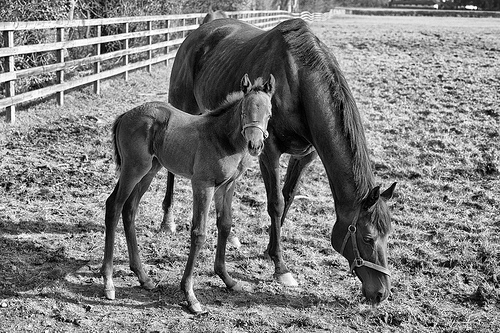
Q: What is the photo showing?
A: It is showing a pasture.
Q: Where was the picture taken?
A: It was taken at the pasture.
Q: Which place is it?
A: It is a pasture.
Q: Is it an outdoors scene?
A: Yes, it is outdoors.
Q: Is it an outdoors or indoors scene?
A: It is outdoors.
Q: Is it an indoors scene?
A: No, it is outdoors.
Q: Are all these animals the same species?
A: Yes, all the animals are horses.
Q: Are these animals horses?
A: Yes, all the animals are horses.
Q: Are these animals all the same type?
A: Yes, all the animals are horses.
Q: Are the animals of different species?
A: No, all the animals are horses.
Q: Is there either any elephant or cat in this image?
A: No, there are no cats or elephants.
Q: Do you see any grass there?
A: Yes, there is grass.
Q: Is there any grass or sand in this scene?
A: Yes, there is grass.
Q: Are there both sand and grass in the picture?
A: No, there is grass but no sand.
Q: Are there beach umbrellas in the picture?
A: No, there are no beach umbrellas.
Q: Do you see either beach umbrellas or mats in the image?
A: No, there are no beach umbrellas or mats.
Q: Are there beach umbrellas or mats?
A: No, there are no beach umbrellas or mats.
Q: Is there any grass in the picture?
A: Yes, there is grass.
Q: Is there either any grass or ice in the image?
A: Yes, there is grass.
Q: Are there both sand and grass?
A: No, there is grass but no sand.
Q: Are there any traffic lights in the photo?
A: No, there are no traffic lights.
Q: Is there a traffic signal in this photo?
A: No, there are no traffic lights.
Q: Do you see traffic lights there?
A: No, there are no traffic lights.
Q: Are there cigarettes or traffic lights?
A: No, there are no traffic lights or cigarettes.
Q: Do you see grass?
A: Yes, there is grass.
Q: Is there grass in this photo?
A: Yes, there is grass.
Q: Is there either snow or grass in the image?
A: Yes, there is grass.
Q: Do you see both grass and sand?
A: No, there is grass but no sand.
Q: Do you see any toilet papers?
A: No, there are no toilet papers.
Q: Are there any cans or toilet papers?
A: No, there are no toilet papers or cans.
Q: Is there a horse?
A: Yes, there is a horse.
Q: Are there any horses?
A: Yes, there is a horse.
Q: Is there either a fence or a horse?
A: Yes, there is a horse.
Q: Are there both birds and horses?
A: No, there is a horse but no birds.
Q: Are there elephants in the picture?
A: No, there are no elephants.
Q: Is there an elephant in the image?
A: No, there are no elephants.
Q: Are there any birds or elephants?
A: No, there are no elephants or birds.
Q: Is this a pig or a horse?
A: This is a horse.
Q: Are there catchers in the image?
A: No, there are no catchers.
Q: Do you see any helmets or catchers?
A: No, there are no catchers or helmets.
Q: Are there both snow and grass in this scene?
A: No, there is grass but no snow.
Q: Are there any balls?
A: No, there are no balls.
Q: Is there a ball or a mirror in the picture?
A: No, there are no balls or mirrors.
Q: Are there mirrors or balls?
A: No, there are no balls or mirrors.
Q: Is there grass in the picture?
A: Yes, there is grass.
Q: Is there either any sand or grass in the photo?
A: Yes, there is grass.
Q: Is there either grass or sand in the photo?
A: Yes, there is grass.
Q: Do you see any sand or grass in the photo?
A: Yes, there is grass.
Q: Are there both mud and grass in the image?
A: No, there is grass but no mud.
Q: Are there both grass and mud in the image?
A: No, there is grass but no mud.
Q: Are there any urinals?
A: No, there are no urinals.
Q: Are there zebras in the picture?
A: No, there are no zebras.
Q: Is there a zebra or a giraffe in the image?
A: No, there are no zebras or giraffes.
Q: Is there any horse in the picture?
A: Yes, there is a horse.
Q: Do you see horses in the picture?
A: Yes, there is a horse.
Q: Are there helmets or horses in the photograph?
A: Yes, there is a horse.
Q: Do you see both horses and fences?
A: Yes, there are both a horse and a fence.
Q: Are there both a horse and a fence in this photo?
A: Yes, there are both a horse and a fence.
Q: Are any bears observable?
A: No, there are no bears.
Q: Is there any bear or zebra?
A: No, there are no bears or zebras.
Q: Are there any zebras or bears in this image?
A: No, there are no bears or zebras.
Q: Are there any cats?
A: No, there are no cats.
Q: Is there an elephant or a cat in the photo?
A: No, there are no cats or elephants.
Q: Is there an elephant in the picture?
A: No, there are no elephants.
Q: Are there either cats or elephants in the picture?
A: No, there are no elephants or cats.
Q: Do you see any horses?
A: Yes, there is a horse.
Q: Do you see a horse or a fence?
A: Yes, there is a horse.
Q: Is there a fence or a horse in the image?
A: Yes, there is a horse.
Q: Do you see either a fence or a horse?
A: Yes, there is a horse.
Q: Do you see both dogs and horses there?
A: No, there is a horse but no dogs.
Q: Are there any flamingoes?
A: No, there are no flamingoes.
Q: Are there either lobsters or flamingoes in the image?
A: No, there are no flamingoes or lobsters.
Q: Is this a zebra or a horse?
A: This is a horse.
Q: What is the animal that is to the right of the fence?
A: The animal is a horse.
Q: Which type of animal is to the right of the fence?
A: The animal is a horse.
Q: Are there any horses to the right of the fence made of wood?
A: Yes, there is a horse to the right of the fence.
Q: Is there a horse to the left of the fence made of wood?
A: No, the horse is to the right of the fence.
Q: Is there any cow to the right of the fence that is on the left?
A: No, there is a horse to the right of the fence.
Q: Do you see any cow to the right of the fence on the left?
A: No, there is a horse to the right of the fence.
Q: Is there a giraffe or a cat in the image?
A: No, there are no cats or giraffes.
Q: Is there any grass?
A: Yes, there is grass.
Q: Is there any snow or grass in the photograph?
A: Yes, there is grass.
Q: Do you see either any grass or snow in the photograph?
A: Yes, there is grass.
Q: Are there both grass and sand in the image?
A: No, there is grass but no sand.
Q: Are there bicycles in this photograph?
A: No, there are no bicycles.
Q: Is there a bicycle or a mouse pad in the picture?
A: No, there are no bicycles or mouse pads.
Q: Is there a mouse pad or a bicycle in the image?
A: No, there are no bicycles or mouse pads.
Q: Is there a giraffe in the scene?
A: No, there are no giraffes.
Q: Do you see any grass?
A: Yes, there is grass.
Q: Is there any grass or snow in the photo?
A: Yes, there is grass.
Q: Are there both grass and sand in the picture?
A: No, there is grass but no sand.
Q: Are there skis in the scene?
A: No, there are no skis.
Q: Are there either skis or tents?
A: No, there are no skis or tents.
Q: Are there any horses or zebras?
A: Yes, there is a horse.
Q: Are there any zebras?
A: No, there are no zebras.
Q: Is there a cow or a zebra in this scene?
A: No, there are no zebras or cows.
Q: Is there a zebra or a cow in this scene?
A: No, there are no zebras or cows.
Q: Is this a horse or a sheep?
A: This is a horse.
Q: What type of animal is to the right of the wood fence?
A: The animal is a horse.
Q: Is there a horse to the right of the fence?
A: Yes, there is a horse to the right of the fence.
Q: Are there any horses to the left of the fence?
A: No, the horse is to the right of the fence.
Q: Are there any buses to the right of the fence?
A: No, there is a horse to the right of the fence.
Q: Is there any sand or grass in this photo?
A: Yes, there is grass.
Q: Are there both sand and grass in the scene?
A: No, there is grass but no sand.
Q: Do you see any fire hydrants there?
A: No, there are no fire hydrants.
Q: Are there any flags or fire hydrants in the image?
A: No, there are no fire hydrants or flags.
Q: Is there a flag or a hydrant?
A: No, there are no fire hydrants or flags.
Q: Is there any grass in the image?
A: Yes, there is grass.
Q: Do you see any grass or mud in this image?
A: Yes, there is grass.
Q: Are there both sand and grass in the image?
A: No, there is grass but no sand.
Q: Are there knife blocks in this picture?
A: No, there are no knife blocks.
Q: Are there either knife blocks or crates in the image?
A: No, there are no knife blocks or crates.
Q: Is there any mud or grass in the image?
A: Yes, there is grass.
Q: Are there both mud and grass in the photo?
A: No, there is grass but no mud.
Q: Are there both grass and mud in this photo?
A: No, there is grass but no mud.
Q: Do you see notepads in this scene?
A: No, there are no notepads.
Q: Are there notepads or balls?
A: No, there are no notepads or balls.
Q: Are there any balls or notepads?
A: No, there are no notepads or balls.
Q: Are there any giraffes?
A: No, there are no giraffes.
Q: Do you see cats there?
A: No, there are no cats.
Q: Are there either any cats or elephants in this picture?
A: No, there are no cats or elephants.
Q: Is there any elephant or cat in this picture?
A: No, there are no cats or elephants.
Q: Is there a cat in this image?
A: No, there are no cats.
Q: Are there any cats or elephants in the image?
A: No, there are no cats or elephants.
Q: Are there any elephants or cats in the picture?
A: No, there are no cats or elephants.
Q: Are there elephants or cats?
A: No, there are no cats or elephants.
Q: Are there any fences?
A: Yes, there is a fence.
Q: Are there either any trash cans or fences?
A: Yes, there is a fence.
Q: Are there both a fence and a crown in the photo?
A: No, there is a fence but no crowns.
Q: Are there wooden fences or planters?
A: Yes, there is a wood fence.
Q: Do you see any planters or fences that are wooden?
A: Yes, the fence is wooden.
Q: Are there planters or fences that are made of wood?
A: Yes, the fence is made of wood.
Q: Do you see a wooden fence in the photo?
A: Yes, there is a wood fence.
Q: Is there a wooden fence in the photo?
A: Yes, there is a wood fence.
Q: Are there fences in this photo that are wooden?
A: Yes, there is a fence that is wooden.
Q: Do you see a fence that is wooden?
A: Yes, there is a fence that is wooden.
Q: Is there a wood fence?
A: Yes, there is a fence that is made of wood.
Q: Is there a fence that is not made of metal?
A: Yes, there is a fence that is made of wood.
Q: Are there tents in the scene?
A: No, there are no tents.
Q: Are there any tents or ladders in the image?
A: No, there are no tents or ladders.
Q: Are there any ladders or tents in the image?
A: No, there are no tents or ladders.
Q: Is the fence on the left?
A: Yes, the fence is on the left of the image.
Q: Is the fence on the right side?
A: No, the fence is on the left of the image.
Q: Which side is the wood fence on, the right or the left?
A: The fence is on the left of the image.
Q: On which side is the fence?
A: The fence is on the left of the image.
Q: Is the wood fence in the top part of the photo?
A: Yes, the fence is in the top of the image.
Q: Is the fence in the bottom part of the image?
A: No, the fence is in the top of the image.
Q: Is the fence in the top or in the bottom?
A: The fence is in the top of the image.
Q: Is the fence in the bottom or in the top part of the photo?
A: The fence is in the top of the image.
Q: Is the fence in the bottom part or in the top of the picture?
A: The fence is in the top of the image.